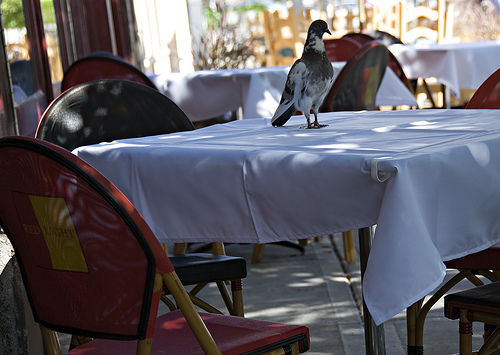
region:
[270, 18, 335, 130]
a gray and white bird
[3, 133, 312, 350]
a red and yellow chair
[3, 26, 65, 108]
two windows on a building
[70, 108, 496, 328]
a white tablecloth on a table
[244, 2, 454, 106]
brown chairs by a table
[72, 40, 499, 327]
tables with white tableclothes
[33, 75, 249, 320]
a black and red chair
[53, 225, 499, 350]
a grey cement ground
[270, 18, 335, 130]
a pigeon on a table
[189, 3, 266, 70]
A brown and green bush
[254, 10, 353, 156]
A bird on a table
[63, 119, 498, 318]
a large white table cloth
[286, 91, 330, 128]
two birds feet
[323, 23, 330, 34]
a birds beak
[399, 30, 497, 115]
white cloth covered table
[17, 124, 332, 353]
red cloth covered chair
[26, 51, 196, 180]
top back of a chair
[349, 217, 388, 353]
wooden table leg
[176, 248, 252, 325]
seat of a chair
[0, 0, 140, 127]
large window on building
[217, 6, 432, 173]
A pigeon standing on a table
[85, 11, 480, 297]
The tablecloth is blue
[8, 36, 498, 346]
There are four chairs around the table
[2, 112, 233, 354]
The chairs have red backs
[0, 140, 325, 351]
The chairs are made of wood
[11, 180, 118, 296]
A yellow tag on the back of the chair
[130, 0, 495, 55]
Sunshine streams in from outside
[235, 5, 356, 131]
The pigeon is dark grey and white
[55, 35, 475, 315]
The tablecloth has fold lines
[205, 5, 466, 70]
There are high-backed chairs in the distance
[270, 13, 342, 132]
Bird with grey and white feathers.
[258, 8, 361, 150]
A bird standing on a table.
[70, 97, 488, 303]
A square table.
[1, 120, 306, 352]
A red chair.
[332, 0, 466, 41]
Wooden chairs in the background.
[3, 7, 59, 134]
A glass window on the left side.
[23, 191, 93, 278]
A yellow tage on back of chair.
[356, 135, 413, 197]
Bracket to hold the tablecloth in place.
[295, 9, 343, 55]
The beak of a bird.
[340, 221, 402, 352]
Support leg of a table.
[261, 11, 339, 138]
A grey and white bird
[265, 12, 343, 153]
A bird on the table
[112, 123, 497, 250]
A white table cloth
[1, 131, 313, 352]
A red folding chair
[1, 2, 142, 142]
A glass sliding door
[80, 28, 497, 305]
Three tables outdoors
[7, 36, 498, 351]
Seven chairs are in this picture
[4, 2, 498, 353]
This picture was taken at a restaurant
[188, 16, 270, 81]
A brown bush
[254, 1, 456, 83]
Upside down stools